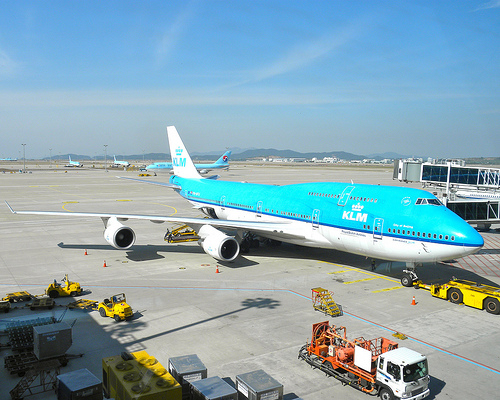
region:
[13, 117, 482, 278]
blue and white airplane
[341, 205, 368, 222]
white lettering on blue background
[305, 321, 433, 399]
white cab of flatbed truck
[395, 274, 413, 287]
front tires of airplane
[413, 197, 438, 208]
front windows of the airplane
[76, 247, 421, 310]
orange safety cones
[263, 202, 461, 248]
row of windows along plane's side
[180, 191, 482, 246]
blue strip along side of airplane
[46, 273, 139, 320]
yellow carts on the tarmac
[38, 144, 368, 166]
mountain range in the far distance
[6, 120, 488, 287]
Plane is landed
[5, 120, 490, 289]
Airplane has landed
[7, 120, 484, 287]
KLM plane has landed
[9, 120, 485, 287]
KLM airplane has landed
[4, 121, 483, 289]
Plane is blue and white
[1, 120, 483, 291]
Airplane is blue and white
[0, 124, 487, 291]
KLM plane is blue and white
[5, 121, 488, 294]
KLM airplane is blue and white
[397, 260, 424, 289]
Landing gear is deployed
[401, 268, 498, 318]
Plane being towed by yellow vehicle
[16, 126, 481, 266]
the plane is on the ground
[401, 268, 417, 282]
the plane has a wheel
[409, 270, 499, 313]
a yellow vehicle pulls plane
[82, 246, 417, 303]
orange cones around plane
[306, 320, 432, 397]
the vehicle is white and orange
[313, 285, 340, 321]
stairs lead to nothing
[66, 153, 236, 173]
planes are in the distance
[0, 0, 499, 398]
the scene take place outdoors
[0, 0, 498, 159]
the clouds are wispy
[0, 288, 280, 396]
a shadow is being cast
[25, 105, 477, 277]
KLM airplane at the tarmac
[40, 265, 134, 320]
two yellow luggage carriers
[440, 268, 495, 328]
yellow luggage carrier parked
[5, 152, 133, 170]
three other airplanes parked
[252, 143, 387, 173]
mountain and homes in distance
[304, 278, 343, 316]
steps to put up to airplane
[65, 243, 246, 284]
shadow of an airplane wing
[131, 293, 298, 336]
shadow of a lightpost on the ground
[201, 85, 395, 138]
blue sky in the distance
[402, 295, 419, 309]
orange cone on the ground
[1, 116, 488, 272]
Jetliner parked on the tarmac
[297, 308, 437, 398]
Fuel pump track on the tarmac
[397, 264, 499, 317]
Yellow towing truck connected to landing gear of plane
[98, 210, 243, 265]
Twin jet engines on a wing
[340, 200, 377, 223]
White colored branding on a blue surface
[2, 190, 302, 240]
Long slender with with an tipped up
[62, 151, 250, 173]
Planes on the tarmac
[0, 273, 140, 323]
Yellow wagon tow trucks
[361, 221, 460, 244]
Row of small sized windows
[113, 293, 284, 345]
Long shadow of a flood light